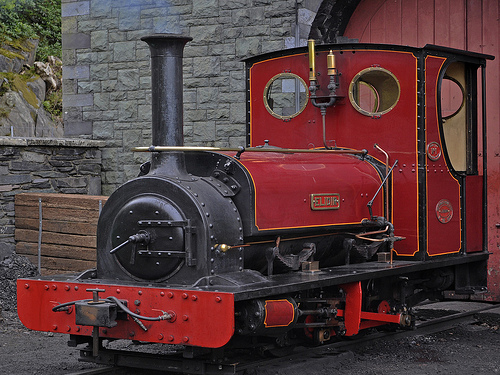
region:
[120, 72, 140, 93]
brick on side of wall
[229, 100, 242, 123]
brick on side of wall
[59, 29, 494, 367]
black and red train engine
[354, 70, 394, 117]
circle window on train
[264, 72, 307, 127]
circle window on train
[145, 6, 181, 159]
steam spout of train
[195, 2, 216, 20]
brick on side of wall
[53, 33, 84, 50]
brick on side of wall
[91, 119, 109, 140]
brick on side of wall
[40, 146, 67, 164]
brick on side of wall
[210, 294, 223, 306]
bolt on the front of a train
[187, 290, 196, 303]
bolt on the front of a train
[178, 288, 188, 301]
bolt on the front of a train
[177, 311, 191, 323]
bolt on the front of a train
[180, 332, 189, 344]
bolt on the front of a train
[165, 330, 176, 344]
bolt on the front of a train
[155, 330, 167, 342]
bolt on the front of a train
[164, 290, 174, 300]
bolt on the front of a train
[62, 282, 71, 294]
bolt on the front of a train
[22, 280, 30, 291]
bolt on the front of a train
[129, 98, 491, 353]
this is a train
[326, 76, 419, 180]
the train is red in color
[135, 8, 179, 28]
this is a fume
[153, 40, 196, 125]
this is a chimney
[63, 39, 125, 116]
this is the wall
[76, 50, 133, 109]
the wall is made of stones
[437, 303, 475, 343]
this is a metal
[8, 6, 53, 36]
this is a tree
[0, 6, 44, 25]
the leaves are green in color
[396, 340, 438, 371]
these are small rocks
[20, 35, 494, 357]
black and red train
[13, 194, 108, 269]
brown wooden slatted bench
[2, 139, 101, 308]
grey rocks stacked on wall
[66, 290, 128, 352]
black metal train hitch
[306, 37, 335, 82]
gold metal train horn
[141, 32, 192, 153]
black iron smoke stack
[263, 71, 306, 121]
round window of train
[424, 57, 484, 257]
red door of train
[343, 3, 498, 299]
red painted barn door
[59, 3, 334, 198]
grey stone brick building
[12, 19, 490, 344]
an old-style train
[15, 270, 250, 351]
the front bumper of a train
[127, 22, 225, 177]
a smokestack on a train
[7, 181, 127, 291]
stacked wood train ties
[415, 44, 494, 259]
the door of a train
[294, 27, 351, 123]
the whistles on a train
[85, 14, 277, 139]
a brick wall behind the train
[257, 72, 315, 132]
a window on the train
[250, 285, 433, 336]
the wheels of the train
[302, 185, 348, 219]
a sign on the side of the train